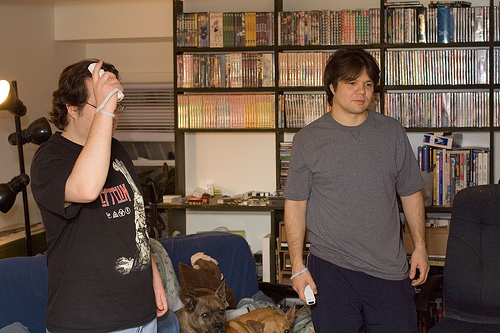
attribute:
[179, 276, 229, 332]
dog — pretty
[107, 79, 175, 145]
blinds — white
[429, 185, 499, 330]
chair — black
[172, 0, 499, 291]
space — full, cluttered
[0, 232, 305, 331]
sofa — blue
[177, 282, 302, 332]
dogs — relaxing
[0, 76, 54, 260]
fixtures — black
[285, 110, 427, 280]
t-shirt — grey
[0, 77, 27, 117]
lights — on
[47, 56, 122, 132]
hair — brown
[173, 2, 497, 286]
bookcase — large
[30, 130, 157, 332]
t shirt — black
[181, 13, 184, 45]
object — little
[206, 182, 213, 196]
object — little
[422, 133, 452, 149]
object — little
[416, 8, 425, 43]
object — little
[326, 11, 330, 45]
object — little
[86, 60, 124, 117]
controller —  wii 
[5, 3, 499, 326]
room — neat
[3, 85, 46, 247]
lamp — black, free standing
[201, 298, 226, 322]
eyes — black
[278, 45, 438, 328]
men — both